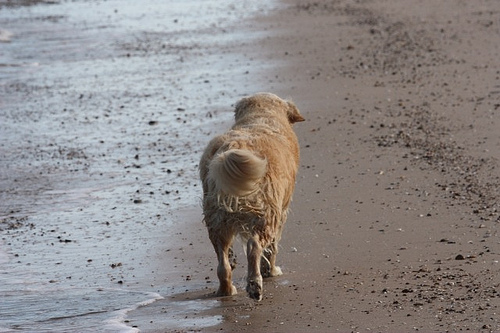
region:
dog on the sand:
[188, 58, 304, 291]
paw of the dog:
[243, 273, 263, 302]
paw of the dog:
[208, 265, 235, 296]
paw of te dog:
[267, 252, 287, 276]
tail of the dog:
[220, 145, 268, 190]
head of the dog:
[219, 90, 304, 123]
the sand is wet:
[37, 192, 127, 264]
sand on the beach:
[294, 248, 363, 300]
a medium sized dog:
[186, 76, 330, 312]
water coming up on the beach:
[11, 2, 285, 326]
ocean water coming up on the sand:
[21, 11, 311, 310]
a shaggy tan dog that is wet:
[200, 82, 308, 300]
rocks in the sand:
[313, 7, 491, 322]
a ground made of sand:
[0, 0, 496, 327]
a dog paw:
[241, 272, 266, 300]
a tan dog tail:
[211, 151, 270, 214]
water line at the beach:
[0, 0, 250, 322]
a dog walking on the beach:
[197, 80, 299, 299]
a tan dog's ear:
[285, 100, 310, 127]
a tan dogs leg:
[201, 200, 244, 305]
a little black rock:
[452, 249, 467, 261]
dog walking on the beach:
[183, 81, 352, 305]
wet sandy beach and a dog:
[61, 45, 426, 268]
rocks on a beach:
[362, 106, 478, 313]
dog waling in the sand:
[196, 81, 388, 285]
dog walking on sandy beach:
[183, 65, 310, 322]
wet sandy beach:
[36, 39, 373, 299]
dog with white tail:
[199, 72, 354, 308]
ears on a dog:
[226, 81, 318, 126]